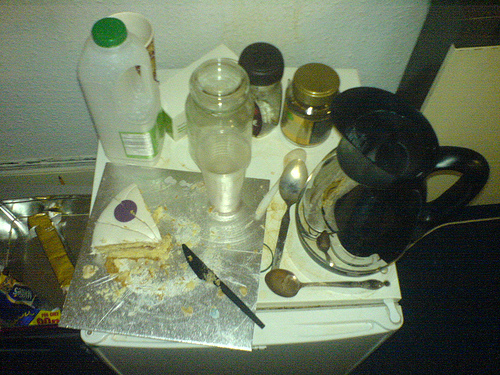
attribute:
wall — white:
[0, 2, 95, 165]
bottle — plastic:
[76, 15, 164, 169]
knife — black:
[181, 242, 265, 328]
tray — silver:
[62, 161, 269, 354]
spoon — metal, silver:
[264, 270, 385, 298]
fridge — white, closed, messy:
[257, 286, 403, 308]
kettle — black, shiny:
[297, 87, 490, 277]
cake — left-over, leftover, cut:
[94, 183, 163, 259]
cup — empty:
[112, 12, 156, 49]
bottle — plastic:
[240, 40, 284, 136]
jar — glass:
[187, 59, 251, 174]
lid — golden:
[294, 63, 341, 102]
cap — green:
[92, 18, 129, 48]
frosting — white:
[92, 183, 162, 245]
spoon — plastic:
[256, 146, 305, 216]